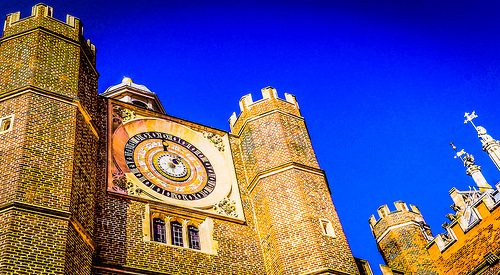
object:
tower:
[218, 86, 360, 275]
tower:
[0, 0, 101, 275]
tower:
[368, 200, 438, 275]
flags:
[225, 86, 297, 129]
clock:
[108, 117, 233, 207]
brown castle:
[4, 0, 500, 275]